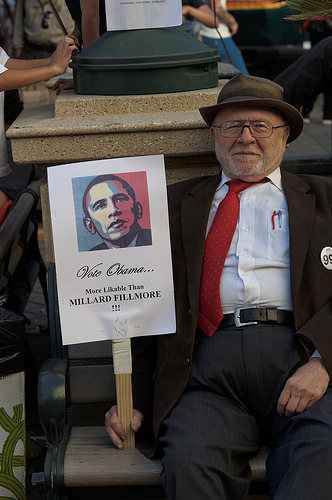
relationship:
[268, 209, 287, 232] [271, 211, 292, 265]
ink pens in shirt pocket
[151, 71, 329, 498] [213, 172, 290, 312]
man has dress shirt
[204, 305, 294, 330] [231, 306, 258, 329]
belt has silver buckle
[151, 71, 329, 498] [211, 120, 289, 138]
man wearing glasses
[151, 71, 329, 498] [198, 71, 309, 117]
man wearing hat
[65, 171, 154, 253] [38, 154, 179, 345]
obama image on poster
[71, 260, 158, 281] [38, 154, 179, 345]
vote obama on poster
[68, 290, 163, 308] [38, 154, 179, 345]
millard fillimore on poster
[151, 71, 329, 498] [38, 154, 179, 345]
man holding poster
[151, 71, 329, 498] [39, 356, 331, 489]
man sitting bench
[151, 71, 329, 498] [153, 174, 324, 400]
man wearing jacket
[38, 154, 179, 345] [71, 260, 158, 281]
poster has vote obama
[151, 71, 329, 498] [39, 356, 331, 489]
man on bench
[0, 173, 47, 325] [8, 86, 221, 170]
other bench near concrete pillar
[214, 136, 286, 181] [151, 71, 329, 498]
beard on man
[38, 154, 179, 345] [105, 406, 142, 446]
poster in right hand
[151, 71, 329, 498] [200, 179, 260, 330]
man has tie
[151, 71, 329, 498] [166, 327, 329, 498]
man wearing pants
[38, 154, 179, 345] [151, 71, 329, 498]
poster with man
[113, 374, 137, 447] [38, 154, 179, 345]
handle on poster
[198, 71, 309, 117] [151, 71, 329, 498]
hat on man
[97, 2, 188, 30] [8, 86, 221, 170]
part sign near concrete pillar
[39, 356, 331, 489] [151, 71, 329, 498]
bench with man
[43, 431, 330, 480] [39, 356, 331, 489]
lower part of bench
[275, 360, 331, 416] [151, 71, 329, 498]
left hand of man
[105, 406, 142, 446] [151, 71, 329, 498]
right hand of man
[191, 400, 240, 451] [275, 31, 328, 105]
part of trouser